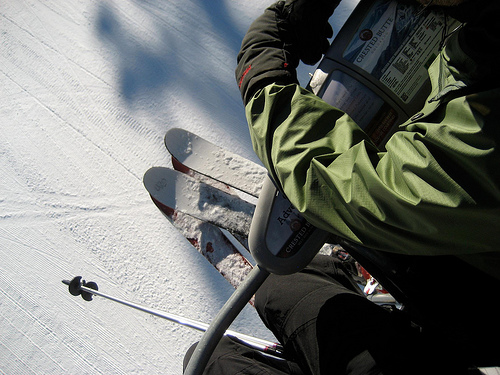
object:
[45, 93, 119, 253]
ground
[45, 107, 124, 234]
snow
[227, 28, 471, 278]
jacket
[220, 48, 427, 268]
skier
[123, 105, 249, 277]
skis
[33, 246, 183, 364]
ski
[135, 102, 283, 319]
ski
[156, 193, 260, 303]
ski lift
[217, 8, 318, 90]
black glove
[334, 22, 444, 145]
snow lift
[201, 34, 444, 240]
jacket